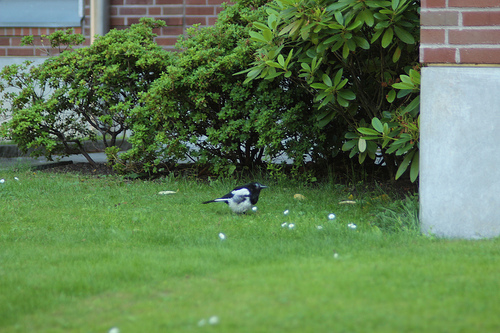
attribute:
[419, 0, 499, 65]
bricks — brown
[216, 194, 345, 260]
white flowers — small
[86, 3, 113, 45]
pipe — metal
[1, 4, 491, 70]
walls — brick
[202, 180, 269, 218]
bird — white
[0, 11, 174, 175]
bush — green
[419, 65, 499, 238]
base — concrete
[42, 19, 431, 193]
trees — tall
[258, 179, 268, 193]
beak — black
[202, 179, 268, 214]
bird — white, black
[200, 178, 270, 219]
bird — black, white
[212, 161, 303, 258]
bird — black and white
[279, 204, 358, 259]
weeds — white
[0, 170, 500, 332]
grass — green, smooth